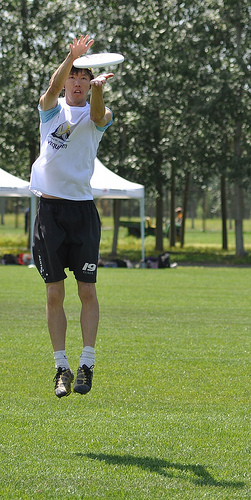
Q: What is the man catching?
A: Frisbee.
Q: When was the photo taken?
A: Daytime.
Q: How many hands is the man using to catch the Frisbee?
A: Two.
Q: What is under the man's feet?
A: Grass.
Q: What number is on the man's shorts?
A: 19.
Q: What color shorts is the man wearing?
A: Black.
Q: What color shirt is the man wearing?
A: White.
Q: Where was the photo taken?
A: In a field.